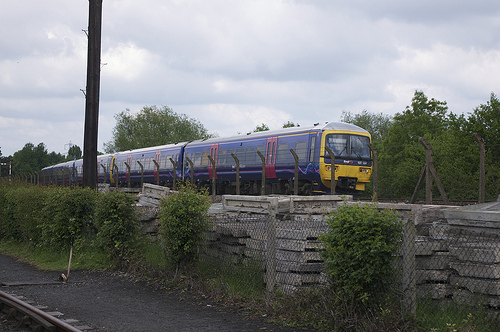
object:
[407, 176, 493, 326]
wall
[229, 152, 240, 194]
wooden posts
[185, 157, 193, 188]
wooden posts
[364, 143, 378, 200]
woodfence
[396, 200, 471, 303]
wall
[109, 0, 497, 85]
clouds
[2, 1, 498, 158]
sky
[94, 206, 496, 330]
fence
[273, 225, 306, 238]
concrete block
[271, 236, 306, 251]
concrete block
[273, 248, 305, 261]
concrete block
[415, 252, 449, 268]
concrete block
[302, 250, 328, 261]
concrete block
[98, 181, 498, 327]
squares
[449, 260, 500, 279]
concrete wall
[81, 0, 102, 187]
pole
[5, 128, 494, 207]
fence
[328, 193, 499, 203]
tracks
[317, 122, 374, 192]
windows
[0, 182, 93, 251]
bush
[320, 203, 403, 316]
bushes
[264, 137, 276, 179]
red door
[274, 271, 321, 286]
concrete wall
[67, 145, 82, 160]
tree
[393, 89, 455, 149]
leaves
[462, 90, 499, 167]
leaves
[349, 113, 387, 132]
leaves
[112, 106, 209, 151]
leaves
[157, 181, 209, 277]
bush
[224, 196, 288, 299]
wall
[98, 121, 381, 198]
train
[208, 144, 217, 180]
doors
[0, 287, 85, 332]
ties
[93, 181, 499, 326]
wall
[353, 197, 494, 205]
train tracks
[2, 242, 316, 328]
ground